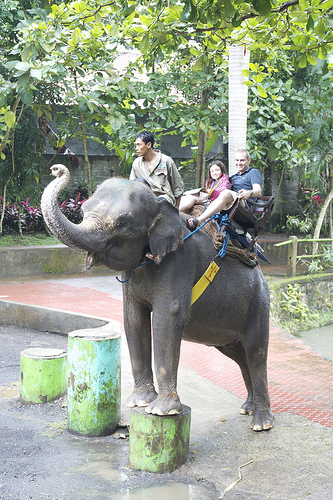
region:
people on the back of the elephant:
[118, 131, 268, 246]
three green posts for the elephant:
[18, 327, 196, 473]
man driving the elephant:
[122, 131, 185, 208]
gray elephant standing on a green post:
[34, 164, 270, 431]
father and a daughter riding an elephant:
[176, 147, 277, 259]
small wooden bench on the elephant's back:
[190, 190, 276, 261]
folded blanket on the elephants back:
[194, 220, 256, 267]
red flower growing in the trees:
[307, 191, 321, 210]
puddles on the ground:
[3, 381, 211, 498]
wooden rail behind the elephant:
[273, 230, 332, 279]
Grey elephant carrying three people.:
[40, 131, 281, 462]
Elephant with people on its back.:
[37, 130, 281, 431]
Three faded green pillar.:
[21, 330, 195, 475]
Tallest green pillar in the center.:
[68, 327, 121, 436]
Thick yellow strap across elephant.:
[180, 260, 220, 314]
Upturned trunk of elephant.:
[38, 159, 83, 254]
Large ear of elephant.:
[147, 202, 183, 264]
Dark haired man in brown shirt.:
[130, 129, 181, 207]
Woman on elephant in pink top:
[178, 150, 229, 211]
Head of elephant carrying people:
[39, 159, 183, 279]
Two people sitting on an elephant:
[36, 149, 277, 433]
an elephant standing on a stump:
[126, 403, 193, 471]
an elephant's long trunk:
[38, 162, 86, 249]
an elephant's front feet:
[124, 381, 176, 410]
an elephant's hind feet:
[236, 393, 273, 427]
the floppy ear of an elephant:
[150, 199, 184, 263]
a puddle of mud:
[110, 481, 213, 498]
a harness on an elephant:
[119, 213, 228, 310]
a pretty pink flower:
[310, 193, 324, 206]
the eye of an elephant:
[119, 221, 124, 226]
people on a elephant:
[102, 112, 286, 397]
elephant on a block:
[31, 124, 270, 489]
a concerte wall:
[10, 248, 82, 278]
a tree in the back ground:
[199, 6, 325, 138]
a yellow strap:
[182, 242, 227, 316]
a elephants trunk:
[39, 155, 151, 273]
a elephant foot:
[241, 408, 282, 437]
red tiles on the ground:
[302, 361, 329, 419]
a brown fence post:
[285, 225, 313, 283]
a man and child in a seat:
[195, 134, 259, 230]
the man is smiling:
[229, 146, 256, 175]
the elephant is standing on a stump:
[135, 369, 180, 458]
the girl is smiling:
[204, 155, 225, 182]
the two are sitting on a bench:
[205, 150, 260, 231]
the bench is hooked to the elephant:
[242, 182, 261, 284]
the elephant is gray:
[226, 270, 248, 296]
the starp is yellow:
[201, 264, 217, 286]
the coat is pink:
[215, 185, 224, 191]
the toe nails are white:
[251, 420, 262, 436]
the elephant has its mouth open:
[77, 242, 102, 273]